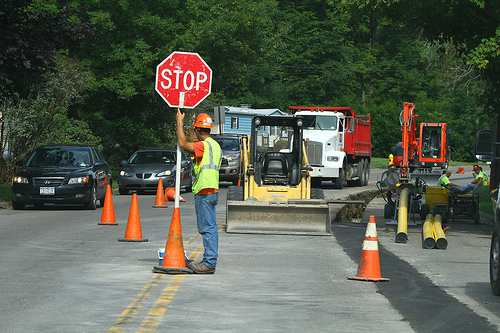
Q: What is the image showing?
A: It is showing a road.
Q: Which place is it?
A: It is a road.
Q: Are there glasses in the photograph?
A: No, there are no glasses.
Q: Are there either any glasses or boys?
A: No, there are no glasses or boys.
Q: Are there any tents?
A: No, there are no tents.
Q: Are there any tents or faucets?
A: No, there are no tents or faucets.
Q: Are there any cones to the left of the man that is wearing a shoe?
A: Yes, there is a cone to the left of the man.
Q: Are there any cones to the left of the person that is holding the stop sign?
A: Yes, there is a cone to the left of the man.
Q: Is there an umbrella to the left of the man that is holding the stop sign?
A: No, there is a cone to the left of the man.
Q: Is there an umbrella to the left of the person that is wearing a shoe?
A: No, there is a cone to the left of the man.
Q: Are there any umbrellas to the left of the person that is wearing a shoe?
A: No, there is a cone to the left of the man.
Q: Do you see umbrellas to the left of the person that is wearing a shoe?
A: No, there is a cone to the left of the man.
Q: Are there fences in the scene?
A: No, there are no fences.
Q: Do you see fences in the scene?
A: No, there are no fences.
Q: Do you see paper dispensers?
A: No, there are no paper dispensers.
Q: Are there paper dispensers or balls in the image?
A: No, there are no paper dispensers or balls.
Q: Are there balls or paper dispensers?
A: No, there are no paper dispensers or balls.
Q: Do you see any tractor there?
A: Yes, there is a tractor.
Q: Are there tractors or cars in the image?
A: Yes, there is a tractor.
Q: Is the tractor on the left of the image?
A: No, the tractor is on the right of the image.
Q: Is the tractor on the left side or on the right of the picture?
A: The tractor is on the right of the image.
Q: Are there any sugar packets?
A: No, there are no sugar packets.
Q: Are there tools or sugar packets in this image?
A: No, there are no sugar packets or tools.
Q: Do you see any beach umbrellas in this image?
A: No, there are no beach umbrellas.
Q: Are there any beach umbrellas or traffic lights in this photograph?
A: No, there are no beach umbrellas or traffic lights.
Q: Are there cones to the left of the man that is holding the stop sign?
A: Yes, there is a cone to the left of the man.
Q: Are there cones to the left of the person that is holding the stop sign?
A: Yes, there is a cone to the left of the man.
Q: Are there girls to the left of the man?
A: No, there is a cone to the left of the man.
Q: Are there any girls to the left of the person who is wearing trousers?
A: No, there is a cone to the left of the man.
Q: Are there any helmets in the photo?
A: Yes, there is a helmet.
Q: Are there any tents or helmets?
A: Yes, there is a helmet.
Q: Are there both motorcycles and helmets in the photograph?
A: No, there is a helmet but no motorcycles.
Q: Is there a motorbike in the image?
A: No, there are no motorcycles.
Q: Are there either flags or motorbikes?
A: No, there are no motorbikes or flags.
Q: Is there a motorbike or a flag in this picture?
A: No, there are no motorcycles or flags.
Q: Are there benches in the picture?
A: No, there are no benches.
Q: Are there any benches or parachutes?
A: No, there are no benches or parachutes.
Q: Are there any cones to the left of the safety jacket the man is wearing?
A: Yes, there is a cone to the left of the safety vest.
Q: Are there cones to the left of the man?
A: Yes, there is a cone to the left of the man.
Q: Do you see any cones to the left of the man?
A: Yes, there is a cone to the left of the man.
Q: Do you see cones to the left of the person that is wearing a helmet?
A: Yes, there is a cone to the left of the man.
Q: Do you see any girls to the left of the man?
A: No, there is a cone to the left of the man.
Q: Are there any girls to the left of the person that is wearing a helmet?
A: No, there is a cone to the left of the man.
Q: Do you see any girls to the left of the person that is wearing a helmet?
A: No, there is a cone to the left of the man.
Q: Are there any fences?
A: No, there are no fences.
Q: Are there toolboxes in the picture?
A: No, there are no toolboxes.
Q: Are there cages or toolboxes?
A: No, there are no toolboxes or cages.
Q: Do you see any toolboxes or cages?
A: No, there are no toolboxes or cages.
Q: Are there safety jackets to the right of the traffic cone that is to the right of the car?
A: Yes, there is a safety jacket to the right of the safety cone.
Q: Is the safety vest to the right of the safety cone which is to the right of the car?
A: Yes, the safety vest is to the right of the cone.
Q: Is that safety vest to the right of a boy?
A: No, the safety vest is to the right of the cone.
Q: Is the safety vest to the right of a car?
A: Yes, the safety vest is to the right of a car.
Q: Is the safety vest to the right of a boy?
A: No, the safety vest is to the right of a car.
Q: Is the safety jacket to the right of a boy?
A: No, the safety jacket is to the right of the car.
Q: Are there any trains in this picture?
A: No, there are no trains.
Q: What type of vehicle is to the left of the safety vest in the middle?
A: The vehicle is a car.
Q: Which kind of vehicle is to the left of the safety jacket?
A: The vehicle is a car.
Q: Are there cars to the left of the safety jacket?
A: Yes, there is a car to the left of the safety jacket.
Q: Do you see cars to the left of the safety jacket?
A: Yes, there is a car to the left of the safety jacket.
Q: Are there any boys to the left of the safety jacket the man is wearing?
A: No, there is a car to the left of the safety jacket.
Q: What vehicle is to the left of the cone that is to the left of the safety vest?
A: The vehicle is a car.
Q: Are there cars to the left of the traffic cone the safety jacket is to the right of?
A: Yes, there is a car to the left of the cone.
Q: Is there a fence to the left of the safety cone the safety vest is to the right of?
A: No, there is a car to the left of the cone.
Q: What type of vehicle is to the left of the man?
A: The vehicle is a car.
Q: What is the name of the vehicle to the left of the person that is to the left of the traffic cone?
A: The vehicle is a car.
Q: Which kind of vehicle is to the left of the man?
A: The vehicle is a car.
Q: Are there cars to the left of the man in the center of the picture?
A: Yes, there is a car to the left of the man.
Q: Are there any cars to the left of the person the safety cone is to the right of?
A: Yes, there is a car to the left of the man.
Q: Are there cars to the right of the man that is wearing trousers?
A: No, the car is to the left of the man.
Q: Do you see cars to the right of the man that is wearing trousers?
A: No, the car is to the left of the man.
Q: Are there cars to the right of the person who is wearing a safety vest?
A: No, the car is to the left of the man.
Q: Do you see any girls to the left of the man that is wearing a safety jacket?
A: No, there is a car to the left of the man.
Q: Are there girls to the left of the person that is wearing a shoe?
A: No, there is a car to the left of the man.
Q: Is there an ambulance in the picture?
A: No, there are no ambulances.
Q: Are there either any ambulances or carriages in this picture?
A: No, there are no ambulances or carriages.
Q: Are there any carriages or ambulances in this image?
A: No, there are no ambulances or carriages.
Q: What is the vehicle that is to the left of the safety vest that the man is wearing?
A: The vehicle is a car.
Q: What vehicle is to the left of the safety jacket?
A: The vehicle is a car.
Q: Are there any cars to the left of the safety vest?
A: Yes, there is a car to the left of the safety vest.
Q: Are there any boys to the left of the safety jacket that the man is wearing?
A: No, there is a car to the left of the safety vest.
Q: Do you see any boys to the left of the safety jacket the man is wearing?
A: No, there is a car to the left of the safety vest.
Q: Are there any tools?
A: No, there are no tools.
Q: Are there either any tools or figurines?
A: No, there are no tools or figurines.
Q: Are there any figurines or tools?
A: No, there are no tools or figurines.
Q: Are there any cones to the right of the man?
A: Yes, there is a cone to the right of the man.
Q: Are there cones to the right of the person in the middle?
A: Yes, there is a cone to the right of the man.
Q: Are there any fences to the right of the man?
A: No, there is a cone to the right of the man.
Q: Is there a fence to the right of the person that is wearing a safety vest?
A: No, there is a cone to the right of the man.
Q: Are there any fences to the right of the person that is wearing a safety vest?
A: No, there is a cone to the right of the man.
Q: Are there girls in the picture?
A: No, there are no girls.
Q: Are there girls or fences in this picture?
A: No, there are no girls or fences.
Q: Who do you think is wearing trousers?
A: The man is wearing trousers.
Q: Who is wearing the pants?
A: The man is wearing trousers.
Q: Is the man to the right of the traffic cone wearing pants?
A: Yes, the man is wearing pants.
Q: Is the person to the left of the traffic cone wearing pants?
A: Yes, the man is wearing pants.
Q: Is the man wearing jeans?
A: No, the man is wearing pants.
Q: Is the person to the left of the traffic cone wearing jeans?
A: No, the man is wearing pants.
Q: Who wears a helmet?
A: The man wears a helmet.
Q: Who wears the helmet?
A: The man wears a helmet.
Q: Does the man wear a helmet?
A: Yes, the man wears a helmet.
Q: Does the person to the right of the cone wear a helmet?
A: Yes, the man wears a helmet.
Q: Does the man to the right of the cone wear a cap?
A: No, the man wears a helmet.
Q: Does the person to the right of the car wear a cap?
A: No, the man wears a helmet.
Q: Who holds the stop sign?
A: The man holds the stop sign.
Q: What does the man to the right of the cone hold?
A: The man holds the stop sign.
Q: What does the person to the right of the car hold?
A: The man holds the stop sign.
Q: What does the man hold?
A: The man holds the stop sign.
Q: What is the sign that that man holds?
A: The sign is a stop sign.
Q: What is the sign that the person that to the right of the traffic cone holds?
A: The sign is a stop sign.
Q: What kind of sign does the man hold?
A: The man holds the stop sign.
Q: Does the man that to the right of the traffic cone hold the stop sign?
A: Yes, the man holds the stop sign.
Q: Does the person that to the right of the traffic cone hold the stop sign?
A: Yes, the man holds the stop sign.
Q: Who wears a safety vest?
A: The man wears a safety vest.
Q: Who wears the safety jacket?
A: The man wears a safety vest.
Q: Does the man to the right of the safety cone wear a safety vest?
A: Yes, the man wears a safety vest.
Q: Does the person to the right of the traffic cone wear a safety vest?
A: Yes, the man wears a safety vest.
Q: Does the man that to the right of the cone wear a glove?
A: No, the man wears a safety vest.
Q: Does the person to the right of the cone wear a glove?
A: No, the man wears a safety vest.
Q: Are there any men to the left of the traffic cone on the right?
A: Yes, there is a man to the left of the traffic cone.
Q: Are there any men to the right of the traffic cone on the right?
A: No, the man is to the left of the traffic cone.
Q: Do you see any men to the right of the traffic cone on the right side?
A: No, the man is to the left of the traffic cone.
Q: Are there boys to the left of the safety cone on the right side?
A: No, there is a man to the left of the traffic cone.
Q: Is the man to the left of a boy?
A: No, the man is to the left of a cone.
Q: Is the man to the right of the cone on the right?
A: No, the man is to the left of the cone.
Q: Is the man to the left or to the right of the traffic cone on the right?
A: The man is to the left of the safety cone.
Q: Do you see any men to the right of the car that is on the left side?
A: Yes, there is a man to the right of the car.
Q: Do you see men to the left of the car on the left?
A: No, the man is to the right of the car.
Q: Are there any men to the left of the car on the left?
A: No, the man is to the right of the car.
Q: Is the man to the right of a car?
A: Yes, the man is to the right of a car.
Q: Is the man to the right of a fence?
A: No, the man is to the right of a car.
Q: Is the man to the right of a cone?
A: Yes, the man is to the right of a cone.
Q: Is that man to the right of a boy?
A: No, the man is to the right of a cone.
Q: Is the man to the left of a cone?
A: No, the man is to the right of a cone.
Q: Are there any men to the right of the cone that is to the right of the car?
A: Yes, there is a man to the right of the traffic cone.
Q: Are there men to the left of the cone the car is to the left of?
A: No, the man is to the right of the traffic cone.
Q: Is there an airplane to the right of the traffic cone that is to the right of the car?
A: No, there is a man to the right of the cone.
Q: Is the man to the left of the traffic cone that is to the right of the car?
A: No, the man is to the right of the safety cone.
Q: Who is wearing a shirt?
A: The man is wearing a shirt.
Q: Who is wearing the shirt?
A: The man is wearing a shirt.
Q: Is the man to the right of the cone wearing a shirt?
A: Yes, the man is wearing a shirt.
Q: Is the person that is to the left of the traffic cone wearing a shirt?
A: Yes, the man is wearing a shirt.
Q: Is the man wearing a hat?
A: No, the man is wearing a shirt.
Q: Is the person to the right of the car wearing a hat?
A: No, the man is wearing a shirt.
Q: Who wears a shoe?
A: The man wears a shoe.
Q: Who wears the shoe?
A: The man wears a shoe.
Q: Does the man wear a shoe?
A: Yes, the man wears a shoe.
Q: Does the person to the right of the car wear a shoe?
A: Yes, the man wears a shoe.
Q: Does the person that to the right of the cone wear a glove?
A: No, the man wears a shoe.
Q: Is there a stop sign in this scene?
A: Yes, there is a stop sign.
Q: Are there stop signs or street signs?
A: Yes, there is a stop sign.